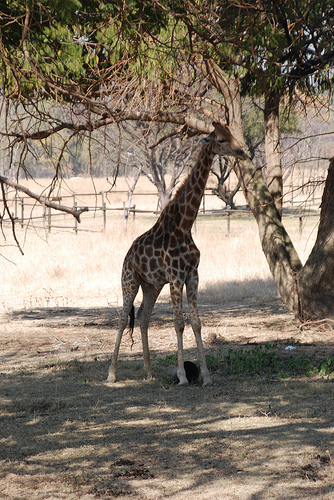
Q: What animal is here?
A: Giraffe.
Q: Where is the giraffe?
A: Under trees.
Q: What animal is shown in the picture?
A: A giraffe.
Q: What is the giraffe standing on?
A: Dirt.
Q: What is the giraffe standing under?
A: A tree.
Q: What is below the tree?
A: A giraffe.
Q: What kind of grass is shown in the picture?
A: Dead grass.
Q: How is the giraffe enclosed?
A: By a large wooden fence.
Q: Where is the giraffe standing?
A: In the shade.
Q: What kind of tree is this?
A: A tree with green leaves.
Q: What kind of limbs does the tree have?
A: Dead ones.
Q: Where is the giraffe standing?
A: In a field.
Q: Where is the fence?
A: Background.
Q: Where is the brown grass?
A: On ground.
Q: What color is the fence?
A: Brown.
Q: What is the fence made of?
A: Wood.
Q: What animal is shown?
A: Giraffe.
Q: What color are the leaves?
A: Green.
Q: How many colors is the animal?
A: 2.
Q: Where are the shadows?
A: On Ground.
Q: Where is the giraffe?
A: In an enclosure.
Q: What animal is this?
A: A giraffe.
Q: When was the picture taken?
A: Daytime.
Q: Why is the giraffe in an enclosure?
A: So it doesn't escape.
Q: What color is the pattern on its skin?
A: Brown.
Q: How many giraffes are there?
A: One.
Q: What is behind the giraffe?
A: A tree.